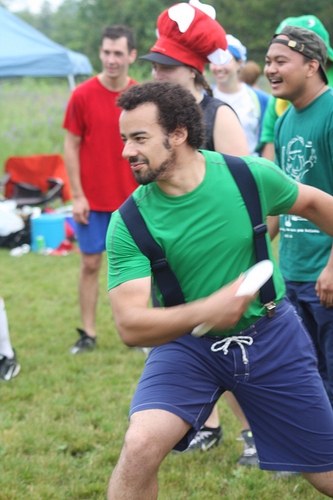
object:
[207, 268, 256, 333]
hand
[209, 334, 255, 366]
string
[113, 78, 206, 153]
hair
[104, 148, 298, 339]
shirt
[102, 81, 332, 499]
man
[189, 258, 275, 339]
frisbee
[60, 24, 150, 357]
man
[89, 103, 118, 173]
red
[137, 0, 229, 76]
hat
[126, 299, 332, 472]
shorts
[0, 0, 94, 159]
tent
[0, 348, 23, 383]
sneaker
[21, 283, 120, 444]
field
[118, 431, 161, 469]
knee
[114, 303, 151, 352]
elbow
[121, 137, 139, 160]
nose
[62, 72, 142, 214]
shirt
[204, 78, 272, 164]
shirt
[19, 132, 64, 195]
chair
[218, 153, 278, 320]
suspenders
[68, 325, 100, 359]
shoe